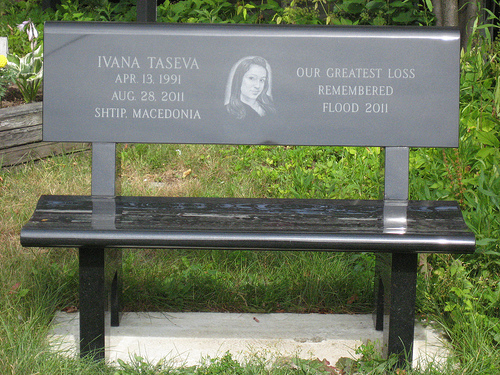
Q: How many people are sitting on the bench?
A: 0.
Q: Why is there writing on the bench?
A: For remembrance.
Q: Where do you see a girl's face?
A: On the bench.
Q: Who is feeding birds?
A: No one.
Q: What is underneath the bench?
A: Cement.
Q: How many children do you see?
A: 0.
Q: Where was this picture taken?
A: At a park.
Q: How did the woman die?
A: In a flood.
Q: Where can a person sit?
A: Bench.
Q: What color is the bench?
A: Gray.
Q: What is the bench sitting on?
A: Concrete.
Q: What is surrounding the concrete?
A: Grass.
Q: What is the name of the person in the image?
A: Ivana Taseva.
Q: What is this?
A: A memorial bench.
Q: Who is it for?
A: Ivana Taseva.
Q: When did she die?
A: Aug 28, 2011.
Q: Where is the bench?
A: Near a park.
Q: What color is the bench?
A: Gray with printing.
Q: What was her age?
A: About 20.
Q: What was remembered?
A: Our greatest loss.